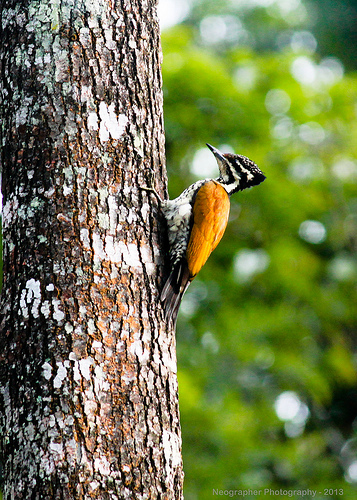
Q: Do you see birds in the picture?
A: Yes, there is a bird.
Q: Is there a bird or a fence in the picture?
A: Yes, there is a bird.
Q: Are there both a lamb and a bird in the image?
A: No, there is a bird but no lambs.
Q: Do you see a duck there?
A: No, there are no ducks.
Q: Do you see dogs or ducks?
A: No, there are no ducks or dogs.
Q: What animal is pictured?
A: The animal is a bird.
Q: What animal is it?
A: The animal is a bird.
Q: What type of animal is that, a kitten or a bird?
A: This is a bird.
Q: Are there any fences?
A: No, there are no fences.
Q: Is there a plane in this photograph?
A: No, there are no airplanes.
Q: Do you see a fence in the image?
A: No, there are no fences.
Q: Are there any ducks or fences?
A: No, there are no fences or ducks.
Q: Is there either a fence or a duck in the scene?
A: No, there are no fences or ducks.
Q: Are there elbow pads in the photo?
A: No, there are no elbow pads.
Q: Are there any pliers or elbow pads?
A: No, there are no elbow pads or pliers.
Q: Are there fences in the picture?
A: No, there are no fences.